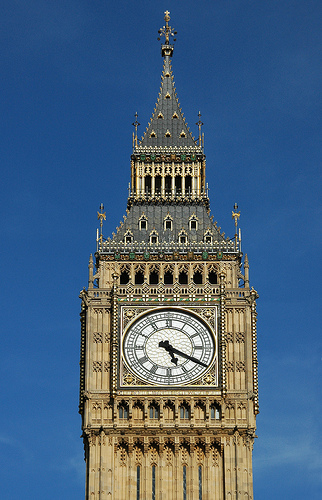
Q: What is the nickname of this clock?
A: Big Ben.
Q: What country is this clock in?
A: England.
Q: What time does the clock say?
A: 5:20.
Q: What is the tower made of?
A: Brick.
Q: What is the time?
A: 5:20.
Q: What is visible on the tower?
A: Clock.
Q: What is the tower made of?
A: Stone.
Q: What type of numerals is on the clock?
A: Roman.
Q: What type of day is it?
A: Sunny.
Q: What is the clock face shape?
A: Round.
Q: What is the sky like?
A: Clear.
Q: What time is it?
A: 5:20.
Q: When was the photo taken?
A: Outdoors.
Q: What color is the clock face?
A: White.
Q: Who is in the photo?
A: No one.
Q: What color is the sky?
A: Blue.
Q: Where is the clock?
A: On the tower.